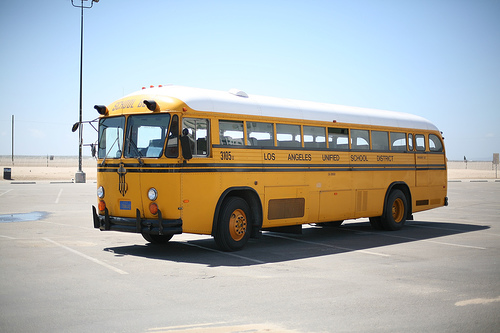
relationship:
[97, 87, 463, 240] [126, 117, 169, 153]
bus has windshield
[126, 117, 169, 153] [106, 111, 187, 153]
windshield in front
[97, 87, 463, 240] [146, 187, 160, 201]
bus has headlight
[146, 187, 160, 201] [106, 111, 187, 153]
headlight in front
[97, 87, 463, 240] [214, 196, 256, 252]
bus has big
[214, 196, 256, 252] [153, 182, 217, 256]
big in front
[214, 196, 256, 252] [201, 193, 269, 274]
big in big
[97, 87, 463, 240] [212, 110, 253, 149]
bus has window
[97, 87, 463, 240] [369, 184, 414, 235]
bus has wheels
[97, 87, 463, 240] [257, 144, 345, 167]
bus has letters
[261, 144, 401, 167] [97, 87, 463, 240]
words on bus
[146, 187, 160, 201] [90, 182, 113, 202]
headlight on right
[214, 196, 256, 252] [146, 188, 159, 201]
big on headlight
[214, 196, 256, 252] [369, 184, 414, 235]
big in back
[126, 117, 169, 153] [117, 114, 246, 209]
front window on left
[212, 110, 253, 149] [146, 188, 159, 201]
window on headlight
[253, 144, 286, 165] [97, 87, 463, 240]
los on bus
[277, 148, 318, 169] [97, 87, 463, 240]
angeles on bus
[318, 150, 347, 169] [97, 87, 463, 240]
unified on th bus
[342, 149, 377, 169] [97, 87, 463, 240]
school on bus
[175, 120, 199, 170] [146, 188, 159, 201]
mirror on headlight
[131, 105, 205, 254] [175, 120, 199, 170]
driver side has a mirror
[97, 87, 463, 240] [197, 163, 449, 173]
bus has black stripes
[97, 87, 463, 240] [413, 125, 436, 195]
bus has emergency exit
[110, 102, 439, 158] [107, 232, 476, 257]
school bus has shadow